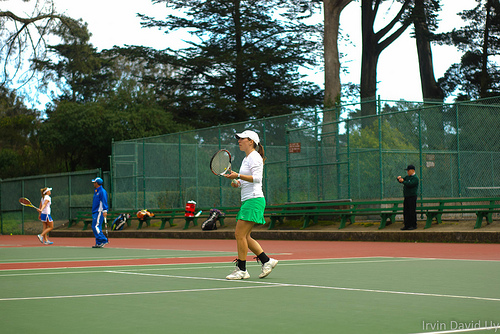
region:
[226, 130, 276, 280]
woman on tennis court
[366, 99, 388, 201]
green pole on chain link fence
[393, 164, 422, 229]
man standing in front of bench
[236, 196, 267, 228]
green skirt on woman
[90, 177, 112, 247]
man in blue and white clothes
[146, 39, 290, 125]
trees behind metal fence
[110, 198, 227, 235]
items on green bench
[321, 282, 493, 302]
white line on green court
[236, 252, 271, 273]
black socks on woman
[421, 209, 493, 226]
legs on green bench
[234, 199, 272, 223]
A short green skirt.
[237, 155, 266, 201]
White jersey in the photo.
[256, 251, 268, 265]
Black socks in the photo.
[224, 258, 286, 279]
White sports shoes in the photo.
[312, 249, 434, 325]
Green tennis ground in the photo.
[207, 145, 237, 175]
A tennis racket in the photo.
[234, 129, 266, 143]
A white cap in the photo.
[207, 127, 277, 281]
A tennis player in the court.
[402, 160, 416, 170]
A black cap in the photo.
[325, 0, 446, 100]
Trees in the photo.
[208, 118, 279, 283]
Woman playing tennis.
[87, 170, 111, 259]
Man in blue suit with white stripe.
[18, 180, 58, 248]
Woman walking away from tennis court.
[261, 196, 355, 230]
Green bench in front of fence.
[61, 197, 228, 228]
Green bench with people's belongings.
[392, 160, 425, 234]
Man taking a photo.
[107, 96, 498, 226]
Steel fence behind the benches.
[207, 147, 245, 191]
Tennis racket in woman's hands.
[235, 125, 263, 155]
White cap on woman's head.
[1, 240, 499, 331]
Green tennis court.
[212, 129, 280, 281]
woman in a green skirt playing tennis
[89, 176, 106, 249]
man in a blue warm-up suit and a hat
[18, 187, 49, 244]
woman in a blue skirt playing tennis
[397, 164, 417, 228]
man with green sweatshirt and black pants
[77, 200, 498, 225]
several green benches by the tennis courts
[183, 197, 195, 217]
red water cooler on the bench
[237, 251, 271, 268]
black socks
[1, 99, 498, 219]
green fence surrounding the tennis courts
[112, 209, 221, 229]
tennis bags leaning against the benches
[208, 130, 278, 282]
woman holding her tennis racket with two hands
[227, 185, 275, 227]
woman's skirt is green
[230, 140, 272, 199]
woman's shirt is white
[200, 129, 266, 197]
woman holding a tennis racket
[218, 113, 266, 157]
woman's hat is white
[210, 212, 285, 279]
woman's socks are black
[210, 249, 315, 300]
woman's shoes are white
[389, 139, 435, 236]
man is wearing a hat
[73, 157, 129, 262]
man's hat is blue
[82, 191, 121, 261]
man's clothes are blue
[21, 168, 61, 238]
woman is wearing a visor